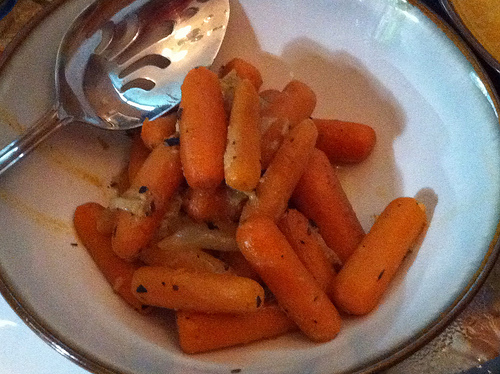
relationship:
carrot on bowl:
[332, 195, 427, 314] [9, 9, 482, 371]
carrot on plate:
[306, 116, 376, 163] [251, 0, 481, 152]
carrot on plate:
[332, 195, 427, 314] [251, 0, 481, 152]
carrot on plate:
[230, 210, 342, 344] [251, 0, 481, 152]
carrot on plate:
[225, 75, 263, 188] [251, 0, 481, 152]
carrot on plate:
[128, 269, 265, 306] [251, 0, 481, 152]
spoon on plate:
[0, 0, 235, 210] [2, 0, 495, 367]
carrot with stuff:
[108, 145, 183, 267] [128, 275, 153, 301]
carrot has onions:
[101, 60, 429, 365] [149, 207, 251, 259]